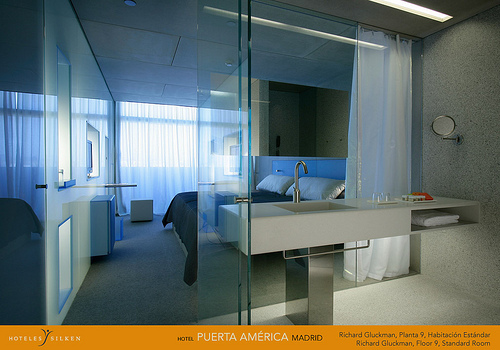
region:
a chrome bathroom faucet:
[284, 157, 309, 204]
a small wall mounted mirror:
[428, 109, 466, 150]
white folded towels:
[411, 206, 459, 228]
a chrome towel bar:
[276, 239, 376, 264]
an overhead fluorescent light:
[361, 0, 458, 27]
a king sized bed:
[157, 170, 347, 265]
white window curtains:
[118, 94, 248, 214]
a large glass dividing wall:
[196, 0, 424, 315]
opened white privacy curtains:
[337, 25, 423, 283]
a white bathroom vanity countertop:
[218, 189, 483, 258]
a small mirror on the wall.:
[422, 111, 474, 148]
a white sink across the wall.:
[227, 158, 399, 251]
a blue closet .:
[263, 155, 338, 176]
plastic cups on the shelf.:
[364, 179, 403, 208]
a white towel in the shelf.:
[410, 207, 477, 232]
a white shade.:
[121, 110, 208, 189]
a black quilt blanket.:
[171, 187, 196, 227]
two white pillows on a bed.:
[240, 166, 350, 204]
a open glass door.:
[168, 0, 257, 335]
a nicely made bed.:
[154, 112, 344, 284]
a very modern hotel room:
[15, 5, 467, 315]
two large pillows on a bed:
[257, 163, 352, 208]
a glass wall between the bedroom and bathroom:
[195, 4, 431, 327]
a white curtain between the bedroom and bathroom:
[324, 9, 424, 289]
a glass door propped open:
[182, 1, 269, 331]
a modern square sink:
[247, 158, 387, 261]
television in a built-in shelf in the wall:
[75, 113, 107, 192]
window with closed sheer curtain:
[116, 86, 261, 224]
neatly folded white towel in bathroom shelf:
[412, 204, 482, 235]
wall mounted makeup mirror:
[418, 101, 472, 158]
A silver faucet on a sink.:
[291, 157, 311, 207]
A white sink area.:
[255, 196, 369, 224]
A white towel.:
[414, 214, 467, 230]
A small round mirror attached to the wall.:
[426, 97, 480, 158]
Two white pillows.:
[253, 169, 344, 200]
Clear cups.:
[365, 189, 394, 205]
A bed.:
[157, 164, 352, 270]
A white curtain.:
[340, 22, 425, 296]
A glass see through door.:
[193, 0, 268, 340]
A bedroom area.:
[99, 84, 397, 288]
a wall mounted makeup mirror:
[427, 112, 466, 145]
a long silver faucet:
[289, 157, 314, 202]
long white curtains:
[113, 102, 198, 212]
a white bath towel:
[411, 215, 460, 227]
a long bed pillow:
[284, 175, 347, 200]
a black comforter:
[159, 190, 297, 289]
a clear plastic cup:
[368, 188, 380, 203]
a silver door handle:
[233, 197, 243, 207]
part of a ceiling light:
[370, 0, 452, 28]